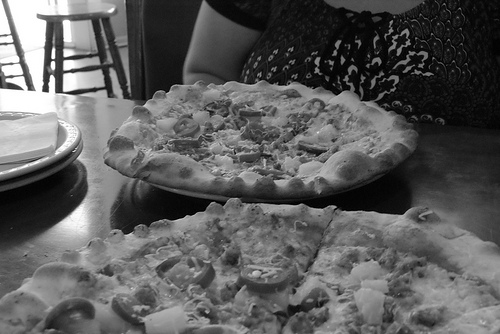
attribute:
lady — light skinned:
[183, 0, 498, 126]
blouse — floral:
[201, 1, 498, 130]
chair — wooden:
[36, 0, 136, 101]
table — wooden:
[0, 87, 499, 332]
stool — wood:
[36, 5, 131, 101]